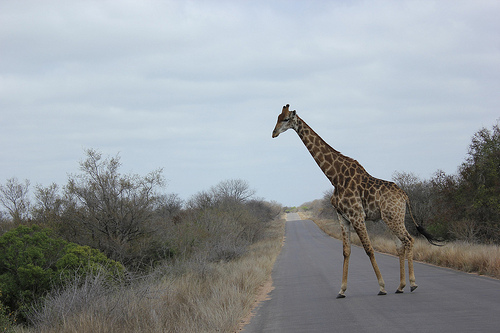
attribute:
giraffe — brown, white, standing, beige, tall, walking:
[267, 94, 454, 297]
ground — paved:
[270, 300, 491, 327]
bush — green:
[4, 220, 125, 321]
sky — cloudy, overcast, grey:
[53, 13, 459, 86]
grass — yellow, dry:
[415, 237, 497, 272]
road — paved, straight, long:
[288, 220, 496, 328]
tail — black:
[403, 189, 458, 254]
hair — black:
[421, 226, 452, 255]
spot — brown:
[340, 174, 352, 191]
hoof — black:
[324, 276, 350, 302]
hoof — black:
[370, 261, 387, 297]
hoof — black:
[390, 270, 411, 298]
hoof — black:
[406, 270, 431, 298]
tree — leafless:
[77, 151, 170, 258]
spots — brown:
[325, 153, 365, 193]